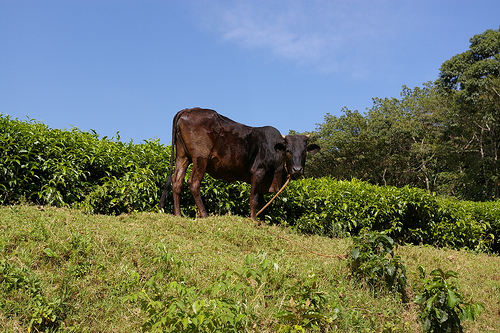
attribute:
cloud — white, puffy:
[211, 26, 358, 85]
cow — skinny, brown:
[176, 95, 308, 217]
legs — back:
[160, 160, 222, 224]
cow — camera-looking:
[160, 99, 324, 223]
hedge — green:
[31, 133, 493, 278]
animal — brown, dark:
[123, 86, 387, 250]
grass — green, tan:
[143, 228, 294, 330]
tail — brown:
[157, 106, 188, 210]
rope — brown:
[249, 155, 291, 229]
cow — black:
[151, 93, 346, 232]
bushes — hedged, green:
[2, 114, 484, 254]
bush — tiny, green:
[345, 226, 406, 297]